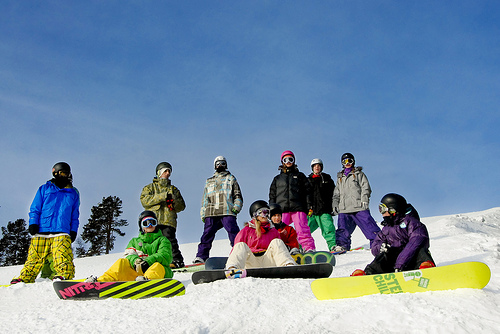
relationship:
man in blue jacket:
[10, 147, 93, 283] [34, 184, 72, 244]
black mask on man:
[46, 164, 86, 202] [10, 147, 93, 283]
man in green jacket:
[121, 218, 174, 285] [134, 230, 172, 263]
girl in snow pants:
[239, 205, 300, 270] [224, 238, 298, 270]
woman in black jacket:
[271, 151, 321, 254] [265, 171, 316, 210]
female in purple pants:
[327, 144, 377, 249] [339, 210, 387, 250]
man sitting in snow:
[85, 210, 173, 282] [198, 300, 282, 322]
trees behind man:
[4, 220, 130, 262] [10, 147, 93, 283]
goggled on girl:
[258, 208, 271, 221] [239, 205, 300, 270]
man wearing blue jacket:
[10, 147, 93, 283] [34, 184, 72, 244]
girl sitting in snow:
[224, 200, 298, 271] [198, 300, 282, 322]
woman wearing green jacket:
[271, 151, 321, 254] [134, 230, 172, 263]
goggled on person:
[258, 208, 271, 221] [106, 209, 187, 319]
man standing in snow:
[10, 162, 80, 284] [198, 300, 282, 322]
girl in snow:
[224, 200, 298, 271] [198, 300, 282, 322]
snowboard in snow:
[312, 272, 491, 308] [198, 300, 282, 322]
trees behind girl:
[0, 195, 129, 266] [224, 200, 298, 271]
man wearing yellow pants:
[10, 147, 93, 283] [26, 234, 81, 279]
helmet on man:
[270, 153, 296, 176] [10, 147, 93, 283]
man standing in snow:
[10, 147, 93, 283] [198, 300, 282, 322]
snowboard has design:
[312, 272, 491, 308] [366, 269, 447, 307]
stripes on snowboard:
[98, 278, 185, 303] [57, 256, 189, 302]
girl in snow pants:
[239, 205, 300, 270] [226, 236, 315, 286]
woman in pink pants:
[271, 151, 321, 254] [282, 206, 326, 251]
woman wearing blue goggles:
[271, 151, 321, 254] [280, 156, 309, 171]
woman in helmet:
[271, 151, 321, 254] [281, 149, 295, 161]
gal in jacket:
[373, 196, 431, 268] [371, 214, 429, 268]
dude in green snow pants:
[306, 150, 340, 255] [303, 216, 341, 249]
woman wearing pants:
[271, 151, 321, 254] [282, 211, 316, 253]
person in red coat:
[271, 203, 300, 249] [278, 220, 300, 249]